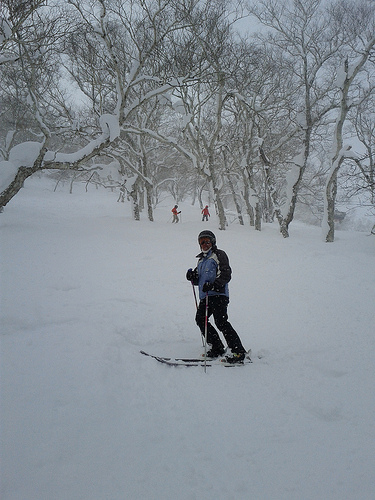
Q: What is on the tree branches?
A: Snow.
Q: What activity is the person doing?
A: Skiing.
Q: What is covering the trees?
A: Snow.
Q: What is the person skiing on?
A: Snow covered ground.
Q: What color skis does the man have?
A: Black.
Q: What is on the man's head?
A: A ski helmet.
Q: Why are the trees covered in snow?
A: It's winter and just snowed.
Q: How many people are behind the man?
A: 2.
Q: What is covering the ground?
A: Snow.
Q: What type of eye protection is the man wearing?
A: Goggles.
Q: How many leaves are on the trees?
A: Zero.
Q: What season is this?
A: Winter.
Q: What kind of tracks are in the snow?
A: Ski tracks.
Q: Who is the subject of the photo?
A: The man.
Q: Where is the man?
A: On the hill.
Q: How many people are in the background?
A: Two.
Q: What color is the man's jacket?
A: Blue and black.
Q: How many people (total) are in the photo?
A: Three.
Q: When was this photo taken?
A: In the daytime.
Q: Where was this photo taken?
A: At a ski resort.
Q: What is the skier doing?
A: Skidding to a stop.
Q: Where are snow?
A: On trees.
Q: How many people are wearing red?
A: Two.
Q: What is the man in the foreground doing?
A: Skiing.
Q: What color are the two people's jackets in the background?
A: Red.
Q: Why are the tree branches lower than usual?
A: The snow and ice are weighing them down.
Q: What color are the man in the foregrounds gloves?
A: Black.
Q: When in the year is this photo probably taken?
A: Winter.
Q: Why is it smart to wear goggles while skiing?
A: To keep snow and other debris out of your eyes.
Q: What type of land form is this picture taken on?
A: A hill.